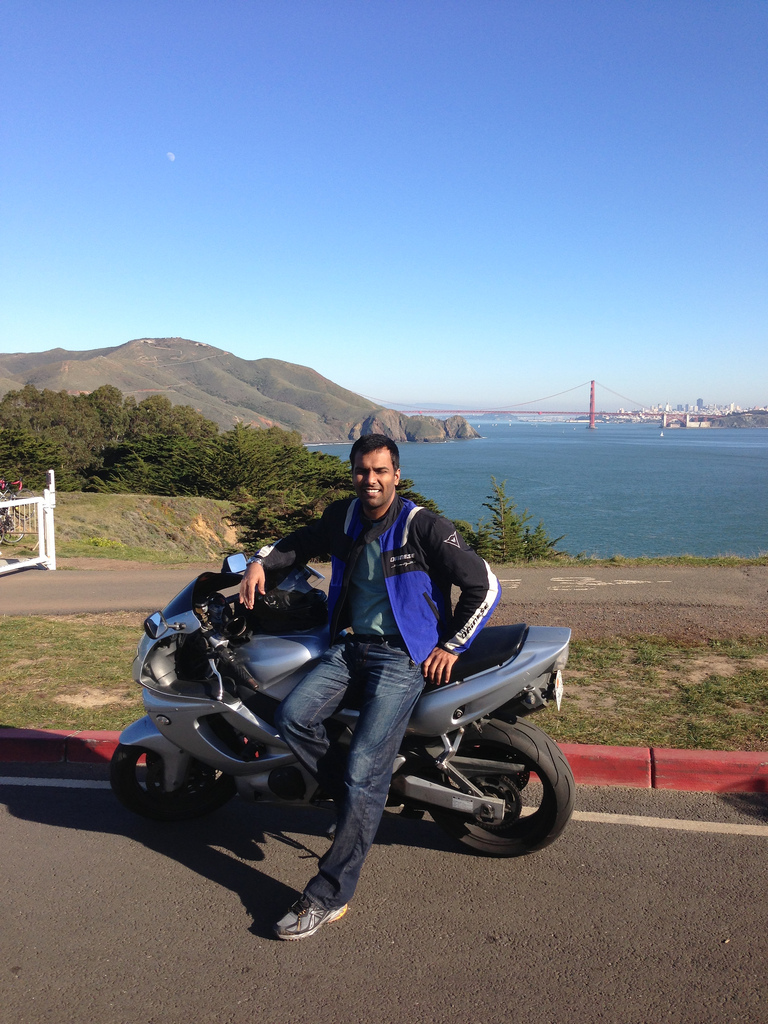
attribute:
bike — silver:
[97, 542, 595, 870]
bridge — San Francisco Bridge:
[394, 402, 722, 421]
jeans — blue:
[281, 641, 431, 897]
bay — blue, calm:
[532, 452, 713, 553]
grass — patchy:
[605, 650, 736, 721]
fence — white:
[10, 480, 70, 567]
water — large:
[546, 455, 670, 541]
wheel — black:
[466, 720, 573, 855]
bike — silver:
[136, 599, 302, 798]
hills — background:
[6, 311, 390, 452]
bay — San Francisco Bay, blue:
[547, 435, 724, 546]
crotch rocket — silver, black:
[112, 543, 574, 857]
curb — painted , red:
[586, 740, 763, 798]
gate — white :
[5, 472, 62, 572]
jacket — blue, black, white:
[253, 488, 507, 656]